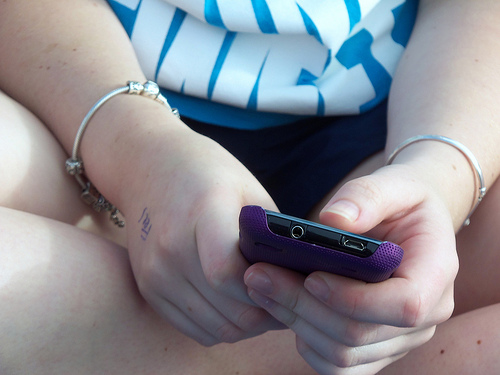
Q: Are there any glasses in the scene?
A: No, there are no glasses.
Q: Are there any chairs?
A: No, there are no chairs.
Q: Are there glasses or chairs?
A: No, there are no chairs or glasses.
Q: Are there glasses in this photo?
A: No, there are no glasses.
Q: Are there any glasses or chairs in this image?
A: No, there are no glasses or chairs.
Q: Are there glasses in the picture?
A: No, there are no glasses.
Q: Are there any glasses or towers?
A: No, there are no glasses or towers.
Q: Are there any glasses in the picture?
A: No, there are no glasses.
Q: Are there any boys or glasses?
A: No, there are no glasses or boys.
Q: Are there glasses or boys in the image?
A: No, there are no glasses or boys.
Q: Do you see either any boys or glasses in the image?
A: No, there are no glasses or boys.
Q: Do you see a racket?
A: No, there are no rackets.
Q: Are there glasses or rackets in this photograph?
A: No, there are no rackets or glasses.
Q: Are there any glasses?
A: No, there are no glasses.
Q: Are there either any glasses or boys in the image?
A: No, there are no glasses or boys.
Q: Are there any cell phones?
A: Yes, there is a cell phone.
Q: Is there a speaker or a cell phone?
A: Yes, there is a cell phone.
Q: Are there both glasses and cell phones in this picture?
A: No, there is a cell phone but no glasses.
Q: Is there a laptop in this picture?
A: No, there are no laptops.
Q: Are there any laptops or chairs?
A: No, there are no laptops or chairs.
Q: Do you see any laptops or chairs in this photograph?
A: No, there are no laptops or chairs.